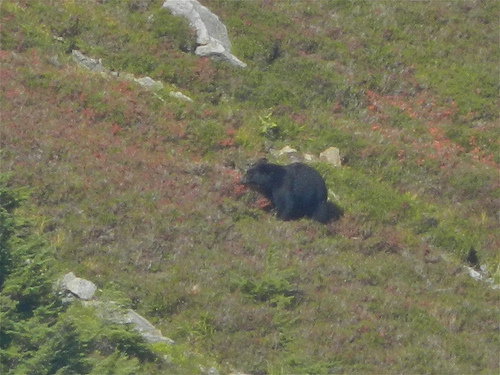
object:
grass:
[242, 0, 500, 375]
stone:
[56, 267, 101, 301]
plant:
[252, 106, 280, 135]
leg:
[269, 196, 278, 210]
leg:
[275, 194, 297, 221]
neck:
[268, 164, 287, 190]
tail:
[323, 195, 329, 203]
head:
[237, 157, 281, 187]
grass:
[0, 0, 235, 374]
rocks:
[45, 44, 113, 78]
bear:
[239, 157, 330, 225]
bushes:
[0, 189, 199, 375]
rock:
[194, 358, 223, 375]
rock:
[139, 76, 166, 93]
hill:
[0, 0, 500, 375]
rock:
[302, 152, 320, 164]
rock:
[53, 267, 101, 301]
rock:
[167, 89, 196, 104]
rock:
[148, 0, 250, 68]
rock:
[318, 145, 344, 166]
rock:
[84, 300, 176, 354]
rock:
[278, 143, 298, 156]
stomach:
[291, 196, 316, 215]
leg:
[311, 199, 330, 225]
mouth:
[241, 180, 256, 186]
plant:
[409, 181, 434, 203]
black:
[280, 174, 321, 207]